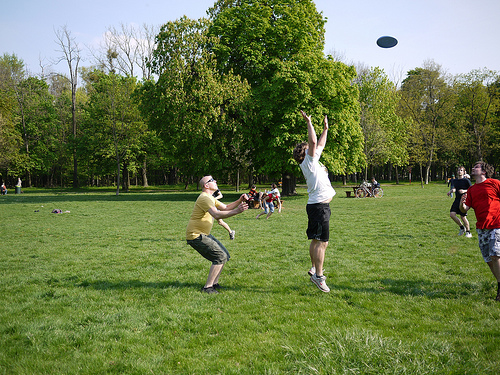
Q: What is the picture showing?
A: It is showing a park.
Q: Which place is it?
A: It is a park.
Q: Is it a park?
A: Yes, it is a park.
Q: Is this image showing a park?
A: Yes, it is showing a park.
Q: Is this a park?
A: Yes, it is a park.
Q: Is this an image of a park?
A: Yes, it is showing a park.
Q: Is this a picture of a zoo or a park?
A: It is showing a park.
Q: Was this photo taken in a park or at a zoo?
A: It was taken at a park.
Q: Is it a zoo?
A: No, it is a park.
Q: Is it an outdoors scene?
A: Yes, it is outdoors.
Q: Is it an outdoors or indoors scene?
A: It is outdoors.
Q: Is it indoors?
A: No, it is outdoors.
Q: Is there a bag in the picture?
A: No, there are no bags.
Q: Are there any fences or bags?
A: No, there are no bags or fences.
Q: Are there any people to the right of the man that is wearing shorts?
A: Yes, there is a person to the right of the man.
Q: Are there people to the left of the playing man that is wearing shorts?
A: No, the person is to the right of the man.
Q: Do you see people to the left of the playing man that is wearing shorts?
A: No, the person is to the right of the man.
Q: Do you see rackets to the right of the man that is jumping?
A: No, there is a person to the right of the man.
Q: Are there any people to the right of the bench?
A: Yes, there is a person to the right of the bench.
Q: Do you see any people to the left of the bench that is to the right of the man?
A: No, the person is to the right of the bench.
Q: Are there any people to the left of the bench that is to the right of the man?
A: No, the person is to the right of the bench.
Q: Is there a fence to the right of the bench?
A: No, there is a person to the right of the bench.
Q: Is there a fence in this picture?
A: No, there are no fences.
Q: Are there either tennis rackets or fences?
A: No, there are no fences or tennis rackets.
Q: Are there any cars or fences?
A: No, there are no fences or cars.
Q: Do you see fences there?
A: No, there are no fences.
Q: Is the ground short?
A: Yes, the ground is short.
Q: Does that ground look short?
A: Yes, the ground is short.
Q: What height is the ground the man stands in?
A: The ground is short.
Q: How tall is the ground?
A: The ground is short.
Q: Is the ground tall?
A: No, the ground is short.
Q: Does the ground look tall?
A: No, the ground is short.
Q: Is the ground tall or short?
A: The ground is short.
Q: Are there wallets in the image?
A: No, there are no wallets.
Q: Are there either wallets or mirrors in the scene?
A: No, there are no wallets or mirrors.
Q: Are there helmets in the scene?
A: No, there are no helmets.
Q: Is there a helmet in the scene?
A: No, there are no helmets.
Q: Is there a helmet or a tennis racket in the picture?
A: No, there are no helmets or rackets.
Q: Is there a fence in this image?
A: No, there are no fences.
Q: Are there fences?
A: No, there are no fences.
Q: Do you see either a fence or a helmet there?
A: No, there are no fences or helmets.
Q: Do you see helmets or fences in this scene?
A: No, there are no fences or helmets.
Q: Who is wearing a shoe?
A: The man is wearing a shoe.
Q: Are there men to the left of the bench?
A: Yes, there is a man to the left of the bench.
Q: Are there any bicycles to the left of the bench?
A: No, there is a man to the left of the bench.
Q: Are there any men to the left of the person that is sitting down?
A: Yes, there is a man to the left of the person.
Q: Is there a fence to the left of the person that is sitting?
A: No, there is a man to the left of the person.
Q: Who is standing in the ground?
A: The man is standing in the ground.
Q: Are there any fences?
A: No, there are no fences.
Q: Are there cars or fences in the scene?
A: No, there are no fences or cars.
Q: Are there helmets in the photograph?
A: No, there are no helmets.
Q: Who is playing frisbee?
A: The man is playing frisbee.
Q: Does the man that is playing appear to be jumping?
A: Yes, the man is jumping.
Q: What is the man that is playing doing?
A: The man is jumping.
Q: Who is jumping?
A: The man is jumping.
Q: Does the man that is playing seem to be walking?
A: No, the man is jumping.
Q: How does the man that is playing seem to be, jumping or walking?
A: The man is jumping.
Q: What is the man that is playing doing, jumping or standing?
A: The man is jumping.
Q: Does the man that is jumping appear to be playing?
A: Yes, the man is playing.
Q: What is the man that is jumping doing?
A: The man is playing.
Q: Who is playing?
A: The man is playing.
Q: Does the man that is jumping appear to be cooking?
A: No, the man is playing.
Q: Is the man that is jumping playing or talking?
A: The man is playing.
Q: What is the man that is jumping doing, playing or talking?
A: The man is playing.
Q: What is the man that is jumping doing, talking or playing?
A: The man is playing.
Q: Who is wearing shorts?
A: The man is wearing shorts.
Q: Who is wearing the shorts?
A: The man is wearing shorts.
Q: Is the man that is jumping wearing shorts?
A: Yes, the man is wearing shorts.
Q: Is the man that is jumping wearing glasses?
A: No, the man is wearing shorts.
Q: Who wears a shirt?
A: The man wears a shirt.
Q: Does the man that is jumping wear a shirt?
A: Yes, the man wears a shirt.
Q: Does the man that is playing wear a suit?
A: No, the man wears a shirt.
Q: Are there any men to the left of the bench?
A: Yes, there is a man to the left of the bench.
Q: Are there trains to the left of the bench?
A: No, there is a man to the left of the bench.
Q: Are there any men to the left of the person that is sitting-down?
A: Yes, there is a man to the left of the person.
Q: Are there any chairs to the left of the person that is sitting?
A: No, there is a man to the left of the person.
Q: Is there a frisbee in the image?
A: Yes, there is a frisbee.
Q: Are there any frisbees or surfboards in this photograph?
A: Yes, there is a frisbee.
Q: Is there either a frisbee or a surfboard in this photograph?
A: Yes, there is a frisbee.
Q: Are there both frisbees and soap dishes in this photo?
A: No, there is a frisbee but no soap dishes.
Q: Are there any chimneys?
A: No, there are no chimneys.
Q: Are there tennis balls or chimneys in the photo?
A: No, there are no chimneys or tennis balls.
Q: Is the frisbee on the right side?
A: Yes, the frisbee is on the right of the image.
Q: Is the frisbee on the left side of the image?
A: No, the frisbee is on the right of the image.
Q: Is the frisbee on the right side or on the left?
A: The frisbee is on the right of the image.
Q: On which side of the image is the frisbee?
A: The frisbee is on the right of the image.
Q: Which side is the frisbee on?
A: The frisbee is on the right of the image.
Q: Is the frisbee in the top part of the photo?
A: Yes, the frisbee is in the top of the image.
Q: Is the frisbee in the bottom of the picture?
A: No, the frisbee is in the top of the image.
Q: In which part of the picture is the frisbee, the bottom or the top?
A: The frisbee is in the top of the image.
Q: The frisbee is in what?
A: The frisbee is in the air.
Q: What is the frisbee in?
A: The frisbee is in the air.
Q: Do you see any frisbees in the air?
A: Yes, there is a frisbee in the air.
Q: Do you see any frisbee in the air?
A: Yes, there is a frisbee in the air.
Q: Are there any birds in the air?
A: No, there is a frisbee in the air.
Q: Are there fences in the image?
A: No, there are no fences.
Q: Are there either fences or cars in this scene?
A: No, there are no fences or cars.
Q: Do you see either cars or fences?
A: No, there are no fences or cars.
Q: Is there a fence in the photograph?
A: No, there are no fences.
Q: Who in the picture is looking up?
A: The man is looking up.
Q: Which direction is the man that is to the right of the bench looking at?
A: The man is looking up.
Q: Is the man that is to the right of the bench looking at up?
A: Yes, the man is looking up.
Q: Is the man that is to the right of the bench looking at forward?
A: No, the man is looking up.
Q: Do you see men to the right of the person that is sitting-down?
A: Yes, there is a man to the right of the person.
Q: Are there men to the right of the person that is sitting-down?
A: Yes, there is a man to the right of the person.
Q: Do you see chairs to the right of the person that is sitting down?
A: No, there is a man to the right of the person.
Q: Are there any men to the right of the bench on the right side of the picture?
A: Yes, there is a man to the right of the bench.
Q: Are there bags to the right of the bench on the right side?
A: No, there is a man to the right of the bench.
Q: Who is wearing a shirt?
A: The man is wearing a shirt.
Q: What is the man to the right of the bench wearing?
A: The man is wearing a shirt.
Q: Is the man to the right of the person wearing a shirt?
A: Yes, the man is wearing a shirt.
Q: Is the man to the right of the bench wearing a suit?
A: No, the man is wearing a shirt.